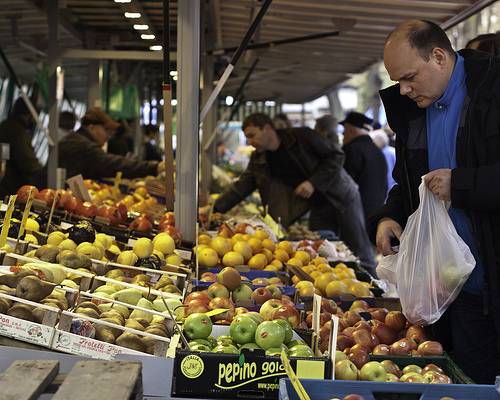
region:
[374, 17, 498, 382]
man with fruit filled plastic bag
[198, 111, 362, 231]
man in brown jacket reaching for some fruit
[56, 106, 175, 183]
man wearing brown cap reaching for fruit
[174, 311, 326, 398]
a box of apples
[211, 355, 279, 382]
writing on side of box of apples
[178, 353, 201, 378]
yellow circle on side of box of apples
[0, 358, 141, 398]
part of a wooden pallet in left foreground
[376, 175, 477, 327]
plastic bag of fruit man is holding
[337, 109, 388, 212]
elderly man in black hat and jacket looking to left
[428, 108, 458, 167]
front part of blue shirt worn by man holding plastic bag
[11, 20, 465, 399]
Open air market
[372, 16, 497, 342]
Man putting fruit in plastic bag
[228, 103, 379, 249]
Man reaching over to get fruit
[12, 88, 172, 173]
Five people on left of market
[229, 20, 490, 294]
Six people on right of market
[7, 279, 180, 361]
Pears on shelf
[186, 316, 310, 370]
Green apples on shelf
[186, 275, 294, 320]
Red and yellow apples on shelf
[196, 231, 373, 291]
Oranges on shelf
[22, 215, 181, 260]
Lemon on shelf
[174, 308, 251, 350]
the apples are green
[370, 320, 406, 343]
this apple is red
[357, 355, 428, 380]
these apples are green and red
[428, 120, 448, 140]
the shirt is blue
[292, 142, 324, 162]
the jacket is brown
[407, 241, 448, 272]
the bag is transparent white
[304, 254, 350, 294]
the oranges are very vibrant in color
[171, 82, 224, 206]
the pole is gray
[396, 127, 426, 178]
the coat is black and gray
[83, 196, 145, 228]
the peppers are bright red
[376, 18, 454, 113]
Man with bald head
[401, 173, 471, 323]
White plastic bag with fruit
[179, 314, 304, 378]
Box of green Pepino apples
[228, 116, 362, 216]
Man with brown jacket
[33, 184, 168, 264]
Boxes of fruits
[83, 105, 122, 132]
Brown hat on man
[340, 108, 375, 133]
Black hat on man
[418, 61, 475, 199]
Man with bright blue shirt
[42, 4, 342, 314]
Farmers market in metal building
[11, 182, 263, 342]
Red yellow and green fruit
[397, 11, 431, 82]
Man is going bald.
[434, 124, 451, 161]
Man wearing blue shirt.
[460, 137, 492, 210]
Man wearing black coat.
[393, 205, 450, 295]
Man holding white bag.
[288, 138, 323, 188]
Person wearing dark coat.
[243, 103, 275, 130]
Man has dark hair.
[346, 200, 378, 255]
Man wearing dark pants.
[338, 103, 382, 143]
Person wearing black hat.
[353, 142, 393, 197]
Man wearing black coat.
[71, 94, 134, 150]
Man wearing cap on head.